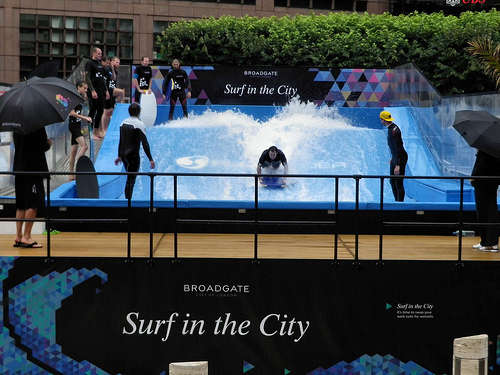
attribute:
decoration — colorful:
[314, 67, 434, 106]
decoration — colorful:
[3, 257, 112, 373]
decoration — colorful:
[271, 347, 440, 373]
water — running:
[118, 97, 401, 197]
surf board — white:
[139, 90, 160, 127]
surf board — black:
[256, 167, 288, 189]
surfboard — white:
[138, 85, 162, 131]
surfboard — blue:
[262, 177, 284, 187]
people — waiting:
[77, 41, 203, 139]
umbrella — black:
[1, 73, 83, 131]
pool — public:
[78, 105, 438, 205]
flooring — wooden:
[4, 229, 493, 261]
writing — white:
[87, 297, 352, 359]